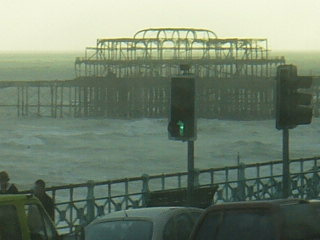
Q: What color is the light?
A: Green.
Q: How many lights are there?
A: Two.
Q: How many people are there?
A: Two.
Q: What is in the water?
A: Construction.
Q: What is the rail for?
A: Safety.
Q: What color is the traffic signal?
A: Green.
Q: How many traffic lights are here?
A: Two.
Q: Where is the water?
A: Past the railing.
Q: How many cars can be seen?
A: Three.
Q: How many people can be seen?
A: Two.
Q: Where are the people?
A: Near the rail on the left side.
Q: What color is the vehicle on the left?
A: Yellow.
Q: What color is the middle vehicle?
A: Grey.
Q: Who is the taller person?
A: The one on the left.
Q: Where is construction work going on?
A: On pier.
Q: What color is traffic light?
A: Green.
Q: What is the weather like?
A: Foggy.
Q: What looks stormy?
A: The sky.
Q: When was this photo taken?
A: Daytime.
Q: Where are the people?
A: Left.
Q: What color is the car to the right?
A: Red.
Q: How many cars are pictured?
A: 3.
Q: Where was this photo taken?
A: Ocean.